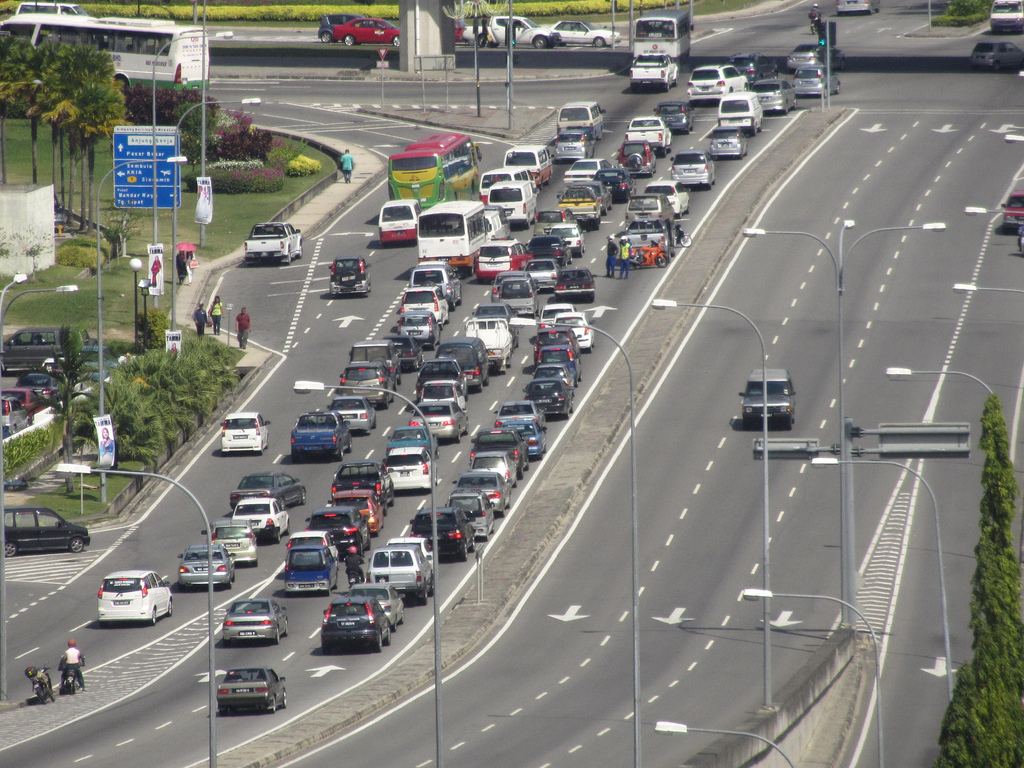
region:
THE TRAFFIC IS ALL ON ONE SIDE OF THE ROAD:
[24, 68, 838, 754]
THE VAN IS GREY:
[721, 349, 811, 470]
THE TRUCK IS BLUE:
[283, 396, 351, 472]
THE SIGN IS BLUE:
[86, 106, 195, 228]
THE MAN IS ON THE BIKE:
[38, 634, 102, 695]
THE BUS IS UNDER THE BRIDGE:
[630, 13, 691, 74]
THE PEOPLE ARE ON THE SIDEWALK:
[159, 238, 258, 353]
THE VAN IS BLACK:
[0, 488, 103, 562]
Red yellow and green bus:
[384, 126, 484, 219]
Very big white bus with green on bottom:
[4, 19, 213, 105]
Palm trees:
[0, 25, 130, 237]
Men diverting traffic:
[599, 228, 642, 282]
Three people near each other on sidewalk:
[190, 289, 251, 350]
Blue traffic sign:
[109, 114, 185, 219]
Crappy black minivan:
[0, 502, 93, 563]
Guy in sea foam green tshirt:
[333, 146, 357, 184]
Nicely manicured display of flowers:
[119, 77, 322, 199]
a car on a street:
[210, 665, 288, 717]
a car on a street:
[320, 598, 393, 657]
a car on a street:
[101, 572, 174, 626]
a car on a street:
[180, 544, 234, 598]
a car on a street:
[208, 521, 256, 564]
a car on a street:
[228, 493, 296, 545]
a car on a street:
[237, 465, 320, 511]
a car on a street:
[385, 446, 436, 501]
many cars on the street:
[62, 214, 677, 718]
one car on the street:
[679, 314, 844, 463]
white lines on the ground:
[622, 449, 743, 577]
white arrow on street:
[520, 572, 622, 652]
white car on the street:
[196, 379, 286, 471]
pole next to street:
[549, 246, 857, 702]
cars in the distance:
[616, 25, 831, 140]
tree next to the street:
[890, 382, 1023, 750]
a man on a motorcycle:
[46, 633, 94, 701]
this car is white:
[367, 432, 447, 491]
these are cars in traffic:
[61, 48, 864, 753]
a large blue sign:
[86, 94, 222, 287]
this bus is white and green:
[1, 12, 271, 115]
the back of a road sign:
[724, 397, 977, 486]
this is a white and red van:
[354, 181, 421, 248]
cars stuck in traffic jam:
[386, 195, 517, 323]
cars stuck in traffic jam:
[327, 481, 388, 533]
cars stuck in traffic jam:
[403, 364, 505, 440]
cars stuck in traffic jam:
[430, 379, 570, 490]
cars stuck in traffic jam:
[397, 168, 554, 299]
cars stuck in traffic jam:
[234, 546, 345, 630]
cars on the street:
[130, 63, 821, 664]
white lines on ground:
[569, 458, 797, 711]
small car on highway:
[193, 650, 310, 740]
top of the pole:
[713, 189, 955, 306]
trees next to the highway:
[24, 282, 227, 545]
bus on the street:
[347, 94, 516, 257]